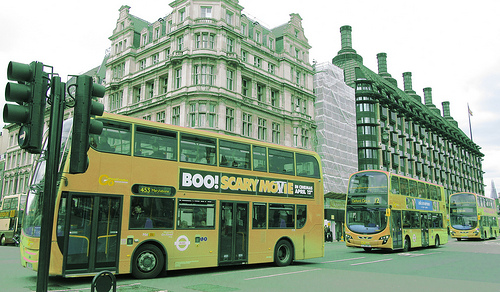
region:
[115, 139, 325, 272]
a double decker bus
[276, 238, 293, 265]
the back tire of the bus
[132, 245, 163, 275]
the front tire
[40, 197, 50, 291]
a black pole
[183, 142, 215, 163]
a window on the bus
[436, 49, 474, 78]
a cloudy sky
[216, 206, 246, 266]
a door on the bus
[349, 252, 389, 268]
a white line in the street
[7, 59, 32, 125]
a traffic signal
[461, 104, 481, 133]
a flag on the building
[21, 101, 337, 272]
bus with upper and lower levels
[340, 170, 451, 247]
bus with upper and lower levels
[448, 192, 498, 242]
bus with upper and lower levels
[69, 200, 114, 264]
doors to the bus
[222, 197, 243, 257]
doors to the bus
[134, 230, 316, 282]
tires on the bus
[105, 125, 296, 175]
windows on upper level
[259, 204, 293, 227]
windows on lower level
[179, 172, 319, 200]
advertisement on the bus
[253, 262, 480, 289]
street where vehicles travel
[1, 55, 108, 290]
Two traffic signals on a black pole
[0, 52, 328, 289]
traffic signals in front of a yellow bus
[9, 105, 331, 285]
Yellow double decker bus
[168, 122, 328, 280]
advertisement on the side of a yellow bus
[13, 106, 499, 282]
three yellow buses in a row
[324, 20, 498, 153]
five green roof top stacks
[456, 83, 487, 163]
flag on top of building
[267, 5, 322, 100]
Dormer of tall building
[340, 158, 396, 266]
front windows of double deck bus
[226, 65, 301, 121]
green trimmed windows and railing on building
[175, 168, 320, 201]
this is a billboard for Scary Movie 5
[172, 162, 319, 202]
an advertisement for Scary Movie 5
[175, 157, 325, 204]
an advertisement for Scary Movie 5 on a bus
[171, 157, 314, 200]
an movie advertisement on a bus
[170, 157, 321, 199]
an advertisement on a double decker bus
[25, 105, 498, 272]
there are three buses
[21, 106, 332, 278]
this is a double decker bus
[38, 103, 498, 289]
there are three double decker buses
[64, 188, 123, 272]
this is the bus entrance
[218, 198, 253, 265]
this is an exit in the middle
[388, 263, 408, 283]
Small part of the green street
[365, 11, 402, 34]
Small patch of the white say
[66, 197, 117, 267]
Front door of the bus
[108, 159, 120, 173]
Yellow part of the bus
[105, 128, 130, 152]
Top window of the bus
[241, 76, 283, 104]
Three windows in the building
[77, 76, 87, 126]
Back section of the stoplight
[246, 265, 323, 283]
Broken white line on the street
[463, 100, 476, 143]
Flag on top of the building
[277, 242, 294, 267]
Back left wheel of the bus